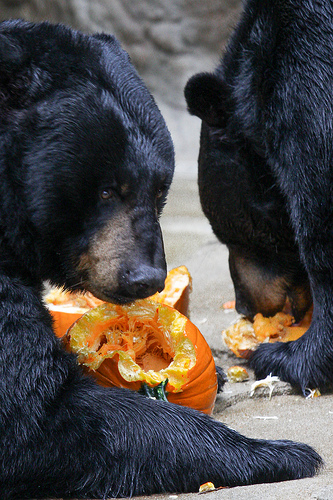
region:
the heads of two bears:
[0, 33, 317, 327]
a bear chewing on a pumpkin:
[194, 146, 314, 337]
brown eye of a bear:
[92, 185, 118, 200]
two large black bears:
[3, 13, 331, 498]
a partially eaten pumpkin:
[58, 292, 235, 437]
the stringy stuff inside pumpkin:
[97, 326, 170, 369]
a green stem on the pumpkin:
[126, 375, 196, 414]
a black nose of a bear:
[116, 266, 178, 309]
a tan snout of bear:
[83, 201, 175, 322]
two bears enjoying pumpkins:
[17, 176, 330, 405]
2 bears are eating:
[7, 24, 312, 357]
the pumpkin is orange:
[47, 275, 225, 405]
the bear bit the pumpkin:
[54, 282, 234, 406]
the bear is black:
[6, 0, 196, 287]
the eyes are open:
[81, 168, 178, 221]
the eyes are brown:
[73, 170, 175, 204]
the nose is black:
[106, 250, 174, 304]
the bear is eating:
[245, 284, 301, 339]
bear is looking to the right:
[23, 39, 191, 312]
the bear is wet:
[5, 53, 283, 498]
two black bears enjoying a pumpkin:
[1, 0, 332, 499]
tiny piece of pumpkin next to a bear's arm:
[198, 482, 218, 494]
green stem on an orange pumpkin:
[138, 376, 171, 401]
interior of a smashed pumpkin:
[67, 300, 196, 384]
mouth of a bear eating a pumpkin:
[268, 292, 304, 324]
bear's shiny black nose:
[117, 265, 166, 299]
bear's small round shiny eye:
[100, 188, 110, 198]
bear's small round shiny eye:
[156, 189, 163, 198]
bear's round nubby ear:
[184, 73, 228, 119]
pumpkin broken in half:
[41, 265, 204, 335]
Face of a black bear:
[28, 100, 177, 312]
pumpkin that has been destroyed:
[54, 278, 229, 429]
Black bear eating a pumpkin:
[210, 179, 324, 361]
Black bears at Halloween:
[10, 31, 323, 410]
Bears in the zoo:
[12, 76, 328, 453]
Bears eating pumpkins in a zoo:
[19, 61, 323, 434]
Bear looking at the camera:
[16, 68, 201, 324]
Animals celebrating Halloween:
[11, 31, 330, 423]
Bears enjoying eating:
[1, 107, 328, 447]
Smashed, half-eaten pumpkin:
[15, 275, 254, 442]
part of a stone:
[196, 469, 213, 490]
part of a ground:
[287, 398, 306, 415]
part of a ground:
[305, 478, 319, 496]